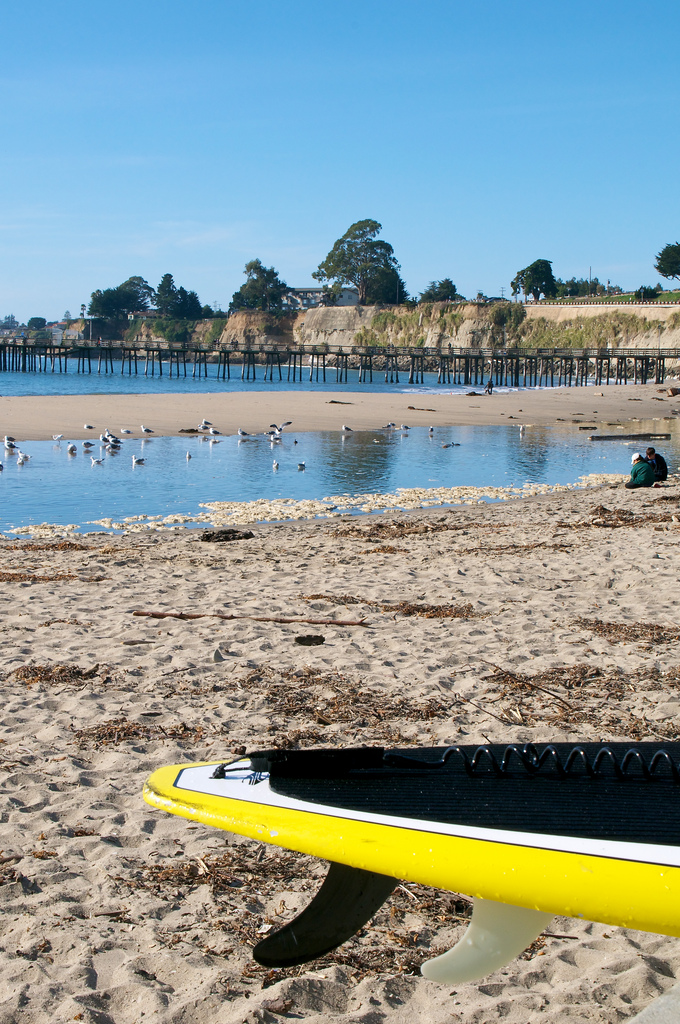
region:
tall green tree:
[308, 212, 407, 307]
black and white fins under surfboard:
[238, 859, 560, 998]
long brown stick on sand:
[121, 599, 372, 633]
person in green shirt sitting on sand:
[620, 446, 656, 492]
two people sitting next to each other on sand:
[623, 443, 674, 493]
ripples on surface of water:
[326, 465, 366, 488]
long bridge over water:
[2, 331, 679, 390]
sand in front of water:
[4, 469, 679, 1022]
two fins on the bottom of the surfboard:
[247, 852, 552, 1003]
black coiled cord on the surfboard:
[205, 743, 674, 779]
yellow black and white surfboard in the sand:
[136, 723, 672, 941]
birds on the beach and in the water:
[23, 396, 469, 472]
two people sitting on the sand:
[610, 440, 667, 497]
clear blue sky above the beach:
[93, 40, 444, 183]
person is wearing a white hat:
[626, 450, 644, 465]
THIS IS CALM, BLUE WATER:
[0, 424, 675, 509]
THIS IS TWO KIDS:
[620, 440, 676, 497]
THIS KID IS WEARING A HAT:
[625, 446, 644, 468]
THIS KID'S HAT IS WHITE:
[621, 450, 645, 468]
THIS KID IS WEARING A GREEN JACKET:
[616, 460, 655, 488]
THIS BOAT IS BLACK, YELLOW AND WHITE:
[133, 708, 677, 969]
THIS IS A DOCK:
[0, 336, 679, 400]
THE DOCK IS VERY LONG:
[0, 334, 678, 398]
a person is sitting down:
[625, 449, 653, 486]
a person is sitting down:
[638, 445, 672, 490]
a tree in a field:
[650, 236, 678, 297]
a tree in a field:
[510, 254, 563, 302]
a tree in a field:
[415, 277, 455, 299]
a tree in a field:
[309, 212, 411, 318]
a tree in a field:
[343, 267, 411, 309]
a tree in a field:
[225, 262, 293, 307]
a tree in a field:
[147, 269, 200, 317]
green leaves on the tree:
[369, 240, 400, 276]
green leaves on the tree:
[334, 211, 368, 263]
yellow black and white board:
[118, 702, 662, 915]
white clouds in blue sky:
[132, 92, 165, 144]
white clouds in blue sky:
[406, 63, 497, 140]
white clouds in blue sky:
[38, 114, 94, 201]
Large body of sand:
[407, 629, 499, 690]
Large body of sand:
[486, 583, 577, 659]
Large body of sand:
[592, 554, 658, 621]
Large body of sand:
[12, 928, 135, 1016]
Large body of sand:
[12, 597, 99, 652]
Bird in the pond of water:
[126, 453, 149, 468]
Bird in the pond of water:
[269, 457, 279, 472]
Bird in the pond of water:
[425, 421, 439, 435]